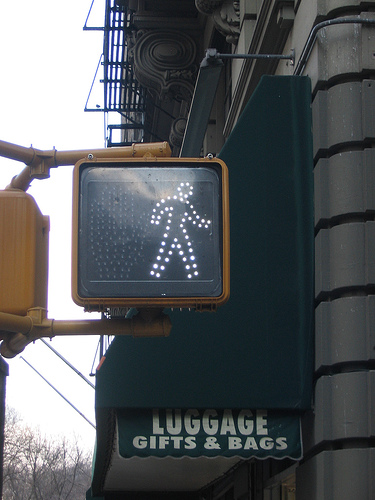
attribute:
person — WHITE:
[146, 178, 214, 287]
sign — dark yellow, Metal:
[68, 150, 234, 308]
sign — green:
[112, 403, 302, 460]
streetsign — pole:
[5, 125, 241, 334]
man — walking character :
[129, 179, 212, 290]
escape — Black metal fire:
[78, 17, 148, 143]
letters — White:
[140, 404, 300, 461]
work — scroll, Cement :
[131, 25, 199, 93]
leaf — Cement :
[217, 7, 248, 24]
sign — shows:
[80, 163, 225, 302]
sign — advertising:
[104, 412, 310, 465]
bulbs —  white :
[145, 183, 217, 281]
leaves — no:
[9, 414, 84, 488]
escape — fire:
[80, 3, 140, 139]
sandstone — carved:
[127, 19, 236, 143]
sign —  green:
[101, 384, 308, 475]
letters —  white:
[129, 411, 304, 470]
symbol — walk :
[155, 166, 208, 289]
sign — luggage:
[121, 416, 307, 463]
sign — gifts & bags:
[132, 434, 292, 453]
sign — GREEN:
[111, 413, 306, 458]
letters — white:
[125, 406, 304, 454]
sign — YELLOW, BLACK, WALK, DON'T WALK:
[4, 132, 225, 328]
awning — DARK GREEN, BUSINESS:
[252, 104, 305, 386]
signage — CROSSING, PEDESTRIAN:
[131, 182, 222, 274]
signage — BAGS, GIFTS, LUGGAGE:
[116, 407, 302, 467]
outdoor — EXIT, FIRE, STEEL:
[80, 9, 135, 135]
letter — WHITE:
[147, 400, 163, 434]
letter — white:
[162, 411, 187, 436]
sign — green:
[117, 407, 312, 463]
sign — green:
[117, 409, 310, 459]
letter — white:
[184, 405, 204, 435]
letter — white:
[198, 407, 225, 437]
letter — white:
[216, 406, 239, 435]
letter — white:
[237, 406, 258, 437]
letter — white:
[253, 406, 271, 436]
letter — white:
[222, 428, 247, 450]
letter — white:
[239, 433, 260, 451]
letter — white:
[258, 432, 273, 451]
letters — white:
[128, 408, 297, 451]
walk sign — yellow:
[68, 147, 235, 305]